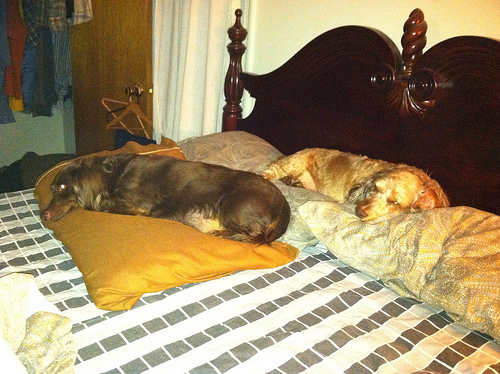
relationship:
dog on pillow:
[256, 142, 448, 232] [180, 118, 499, 339]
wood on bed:
[340, 88, 387, 130] [12, 187, 489, 368]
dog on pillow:
[41, 150, 288, 243] [177, 128, 339, 248]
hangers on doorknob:
[99, 96, 155, 137] [126, 82, 143, 97]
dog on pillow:
[41, 150, 288, 246] [37, 133, 305, 333]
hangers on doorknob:
[101, 96, 153, 139] [125, 87, 143, 97]